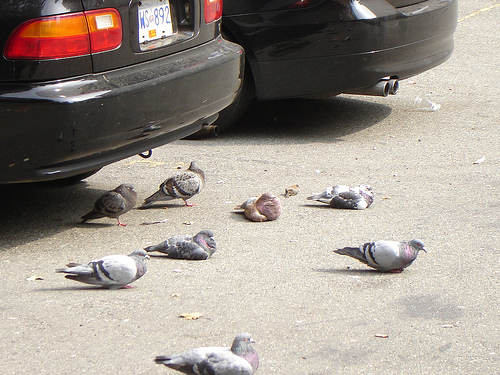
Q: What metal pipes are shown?
A: Exhaust.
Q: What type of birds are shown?
A: Pigeons.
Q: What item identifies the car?
A: The license plate.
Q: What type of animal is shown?
A: A bird.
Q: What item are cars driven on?
A: The road.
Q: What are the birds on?
A: Part of the road.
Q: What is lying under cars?
A: Several pigeons.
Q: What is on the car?
A: Brake and tail light.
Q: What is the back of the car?
A: The bumper.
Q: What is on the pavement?
A: Lots of birs.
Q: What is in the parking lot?
A: Eight pigeons.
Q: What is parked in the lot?
A: Black cars.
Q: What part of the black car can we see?
A: The rear view.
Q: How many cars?
A: 2.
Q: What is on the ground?
A: Birds.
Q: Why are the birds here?
A: For food.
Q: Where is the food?
A: The ground.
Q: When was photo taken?
A: Daytime.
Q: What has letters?
A: Plate.